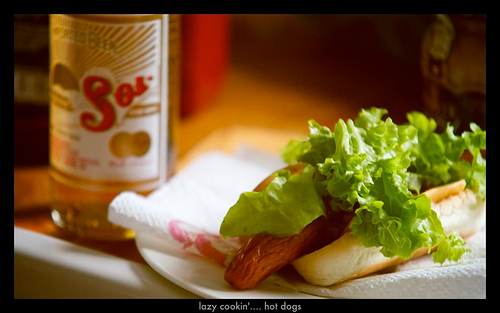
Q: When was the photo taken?
A: Daytime.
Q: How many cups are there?
A: One.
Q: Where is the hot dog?
A: In the bun.